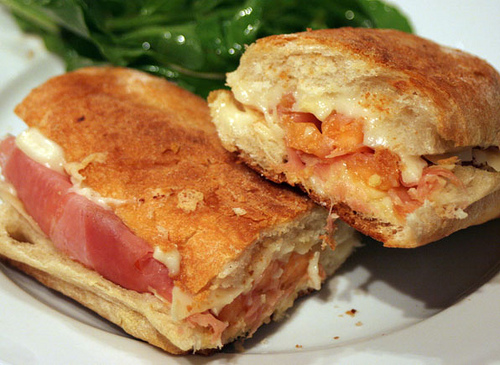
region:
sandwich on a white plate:
[28, 67, 301, 359]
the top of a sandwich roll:
[30, 61, 258, 247]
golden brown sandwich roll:
[46, 79, 285, 284]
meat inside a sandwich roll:
[26, 121, 306, 361]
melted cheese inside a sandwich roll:
[23, 81, 315, 346]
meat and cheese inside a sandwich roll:
[14, 59, 278, 346]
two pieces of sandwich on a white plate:
[30, 31, 494, 363]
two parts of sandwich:
[3, 27, 495, 359]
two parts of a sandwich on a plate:
[19, 28, 472, 360]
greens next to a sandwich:
[33, 4, 441, 103]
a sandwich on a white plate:
[0, 1, 499, 356]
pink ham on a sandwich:
[37, 187, 177, 257]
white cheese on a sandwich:
[366, 114, 411, 178]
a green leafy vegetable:
[18, 0, 420, 83]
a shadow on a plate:
[363, 239, 499, 317]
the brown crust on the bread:
[38, 67, 261, 279]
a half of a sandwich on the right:
[208, 20, 499, 250]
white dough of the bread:
[268, 44, 332, 96]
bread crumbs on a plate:
[304, 305, 377, 353]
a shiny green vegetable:
[28, 0, 248, 73]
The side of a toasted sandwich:
[196, 38, 446, 245]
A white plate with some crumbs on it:
[332, 288, 485, 359]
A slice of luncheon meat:
[22, 158, 152, 270]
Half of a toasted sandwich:
[28, 55, 344, 349]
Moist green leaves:
[103, 5, 240, 65]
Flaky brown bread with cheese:
[30, 73, 207, 191]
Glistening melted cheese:
[286, 85, 423, 135]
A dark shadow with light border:
[370, 260, 479, 305]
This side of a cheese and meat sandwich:
[425, 42, 490, 269]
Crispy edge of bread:
[327, 187, 418, 251]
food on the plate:
[1, 9, 483, 335]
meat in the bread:
[40, 177, 161, 289]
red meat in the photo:
[43, 193, 148, 278]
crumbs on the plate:
[302, 280, 398, 350]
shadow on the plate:
[391, 262, 464, 331]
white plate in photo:
[298, 269, 411, 361]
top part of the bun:
[333, 26, 478, 131]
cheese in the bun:
[246, 51, 425, 185]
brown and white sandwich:
[280, 11, 496, 149]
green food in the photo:
[116, 10, 233, 74]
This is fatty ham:
[82, 220, 116, 286]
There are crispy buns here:
[93, 83, 126, 200]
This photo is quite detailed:
[66, 32, 226, 302]